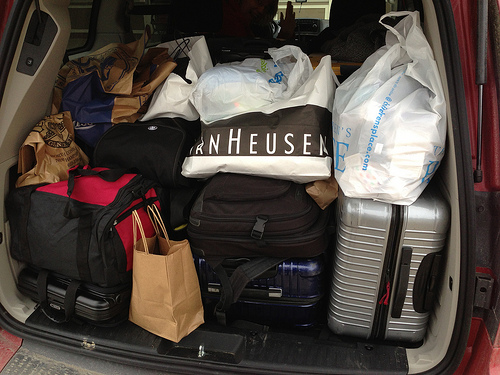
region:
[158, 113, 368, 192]
a white text written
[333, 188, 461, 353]
a laguage bag in car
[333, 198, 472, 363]
a suite case inside the car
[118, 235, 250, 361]
a paper bag in car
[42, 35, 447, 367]
a bunch of laguages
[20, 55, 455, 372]
a group of bags in car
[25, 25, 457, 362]
a car having bags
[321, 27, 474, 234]
a small pocket in suit case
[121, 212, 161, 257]
wire of the paper bag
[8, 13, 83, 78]
side part of the car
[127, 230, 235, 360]
Paper bag in a car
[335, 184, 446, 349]
Silver suitcase in a car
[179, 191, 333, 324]
Two suitcases in a car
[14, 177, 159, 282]
Red and black bag in a car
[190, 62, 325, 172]
Shopping bags in a car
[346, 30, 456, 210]
Blue and white bag in a car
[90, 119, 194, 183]
Black suitcases in a car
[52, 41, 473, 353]
Car full of bags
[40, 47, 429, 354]
Car filled with suitcases and bags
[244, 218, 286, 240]
Black clip on a bag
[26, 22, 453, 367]
a jam packed vehicle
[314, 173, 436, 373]
a large silver and black suitcase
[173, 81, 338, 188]
a brown and white shopping bag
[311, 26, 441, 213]
a white and blue shopping bag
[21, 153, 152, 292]
a red and black duffle bag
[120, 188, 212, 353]
a brown handled bag in front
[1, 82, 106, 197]
a brown paper bag folded over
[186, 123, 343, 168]
white letters on a brown bag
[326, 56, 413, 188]
blue letters on a white bag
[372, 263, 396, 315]
red tag on silver suitcase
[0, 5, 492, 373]
an open van trunk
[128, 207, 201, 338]
the paper bag is brown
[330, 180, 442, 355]
this suitcase is silver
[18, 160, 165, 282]
this bag is red and black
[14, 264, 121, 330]
a briefcase under the bag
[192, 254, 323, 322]
this suitcase is blue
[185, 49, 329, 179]
this bag is plastic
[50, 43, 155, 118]
this paper bag is crumpled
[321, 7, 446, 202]
this bag is blue and white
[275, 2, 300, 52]
a hand by the driver's seat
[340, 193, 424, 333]
silver suitcase in vehicle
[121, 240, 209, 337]
paper bag in vehicle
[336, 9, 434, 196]
plastic bag in vehicle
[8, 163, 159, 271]
red and black duffel bag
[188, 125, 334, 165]
brand info on bag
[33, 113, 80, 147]
logo on a bag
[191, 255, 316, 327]
blue suitcase in vehicle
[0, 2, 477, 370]
back of a vehicle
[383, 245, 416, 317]
handle on a suitcase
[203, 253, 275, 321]
straps to a bag